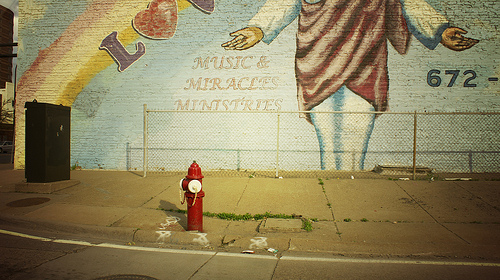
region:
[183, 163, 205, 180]
top of the hydrant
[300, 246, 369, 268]
white paint line on ground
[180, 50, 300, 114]
writing on the wall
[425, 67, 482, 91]
672 on the wall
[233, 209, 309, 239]
grass on the ground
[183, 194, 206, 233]
the hydrant is red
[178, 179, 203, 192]
white part of hydrant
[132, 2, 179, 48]
heart on the wall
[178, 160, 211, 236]
A red and white fire hydrant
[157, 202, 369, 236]
Patches of grass on the sidewalk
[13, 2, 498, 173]
A painting on the side of a building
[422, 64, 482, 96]
"672" written on a building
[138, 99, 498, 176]
A fence in front of the building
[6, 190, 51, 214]
Round manhole on the sidewalk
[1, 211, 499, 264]
The curb of a sidewalk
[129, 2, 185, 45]
A heart picture on building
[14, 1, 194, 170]
A rainbow drawing on the building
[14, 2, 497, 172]
mural on building exterior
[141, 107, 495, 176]
poles on chain link fence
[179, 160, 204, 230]
red and white hydrant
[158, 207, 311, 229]
weeds in sidewalk cracks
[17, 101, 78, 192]
black box on cement base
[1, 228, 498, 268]
white line on street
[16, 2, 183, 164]
painted rainbow on wall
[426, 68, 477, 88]
three numbers painted on wall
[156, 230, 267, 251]
white spraypaint on curb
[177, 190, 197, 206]
chains hanging from hydrant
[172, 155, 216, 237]
red and white fire hydrant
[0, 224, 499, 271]
white line on the side of the road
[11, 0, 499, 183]
painting on the wall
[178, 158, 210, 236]
fire hydrant on the sidewalk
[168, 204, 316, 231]
green grass growing in the cracks of the sidewalk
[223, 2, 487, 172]
painting of Jesus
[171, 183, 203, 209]
chains on the fire hydrant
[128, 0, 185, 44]
red heart painted on the wall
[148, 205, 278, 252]
white paint on the sidewalk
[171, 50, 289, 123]
writing on the wall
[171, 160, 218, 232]
fire hydrant on the sidewalk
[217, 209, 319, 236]
crab grass growing through the cracks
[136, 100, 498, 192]
fence on the wall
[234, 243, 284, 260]
debris on the ground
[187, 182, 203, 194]
white cap on a fire hydrant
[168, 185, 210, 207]
chain on a fire hydrant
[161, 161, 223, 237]
fire hydrant on the sidewalk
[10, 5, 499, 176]
wall painted in blue with rainbow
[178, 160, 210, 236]
red fire hydrant with white caps on sidewalk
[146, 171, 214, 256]
a fire hydrant on sidewalk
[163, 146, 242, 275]
a red and white red hydrant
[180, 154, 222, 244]
a red and white hydrant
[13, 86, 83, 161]
a metal case on the sidewalk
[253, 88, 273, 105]
lettering on the wall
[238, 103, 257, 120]
lettering on the wall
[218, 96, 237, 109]
lettering on the wall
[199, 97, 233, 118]
lettering on the wall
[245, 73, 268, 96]
lettering on the wall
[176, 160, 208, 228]
the hydrant is red in color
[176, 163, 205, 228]
the hydrant is made of metal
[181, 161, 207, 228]
the hydrant releases water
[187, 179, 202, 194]
the hydrant has a white cap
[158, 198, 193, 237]
a shadow is on the pavement